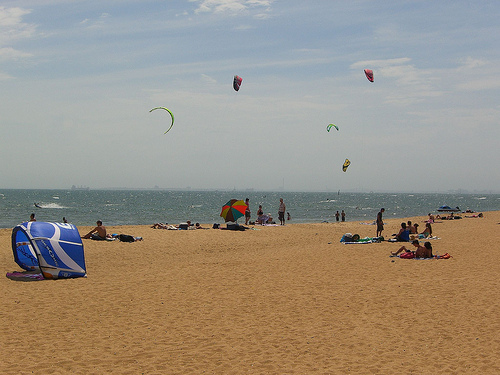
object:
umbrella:
[219, 199, 247, 223]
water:
[1, 190, 498, 230]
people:
[277, 196, 287, 224]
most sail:
[149, 107, 176, 134]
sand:
[204, 270, 315, 320]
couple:
[389, 239, 433, 261]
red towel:
[399, 251, 416, 259]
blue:
[65, 243, 87, 256]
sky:
[1, 0, 498, 191]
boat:
[436, 204, 460, 212]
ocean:
[1, 187, 498, 228]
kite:
[326, 123, 339, 132]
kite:
[341, 159, 350, 172]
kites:
[234, 75, 243, 92]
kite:
[364, 67, 376, 84]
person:
[415, 222, 434, 240]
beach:
[2, 211, 499, 373]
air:
[43, 73, 97, 120]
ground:
[65, 287, 271, 353]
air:
[119, 27, 181, 65]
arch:
[6, 221, 87, 281]